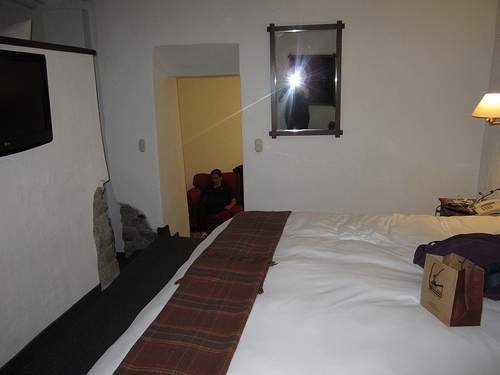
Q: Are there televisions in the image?
A: Yes, there is a television.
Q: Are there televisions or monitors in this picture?
A: Yes, there is a television.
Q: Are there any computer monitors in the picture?
A: No, there are no computer monitors.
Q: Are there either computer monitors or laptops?
A: No, there are no computer monitors or laptops.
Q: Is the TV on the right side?
A: No, the TV is on the left of the image.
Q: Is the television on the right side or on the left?
A: The television is on the left of the image.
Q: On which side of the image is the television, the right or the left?
A: The television is on the left of the image.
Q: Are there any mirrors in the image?
A: Yes, there is a mirror.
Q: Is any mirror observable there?
A: Yes, there is a mirror.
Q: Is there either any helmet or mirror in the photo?
A: Yes, there is a mirror.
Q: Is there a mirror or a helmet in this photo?
A: Yes, there is a mirror.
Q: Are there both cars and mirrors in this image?
A: No, there is a mirror but no cars.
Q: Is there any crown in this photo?
A: No, there are no crowns.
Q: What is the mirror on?
A: The mirror is on the wall.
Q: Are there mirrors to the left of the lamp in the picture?
A: Yes, there is a mirror to the left of the lamp.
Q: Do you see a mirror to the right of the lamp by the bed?
A: No, the mirror is to the left of the lamp.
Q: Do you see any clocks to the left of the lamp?
A: No, there is a mirror to the left of the lamp.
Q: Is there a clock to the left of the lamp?
A: No, there is a mirror to the left of the lamp.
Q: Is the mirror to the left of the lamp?
A: Yes, the mirror is to the left of the lamp.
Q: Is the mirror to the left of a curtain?
A: No, the mirror is to the left of the lamp.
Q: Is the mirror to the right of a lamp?
A: No, the mirror is to the left of a lamp.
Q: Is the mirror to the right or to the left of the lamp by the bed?
A: The mirror is to the left of the lamp.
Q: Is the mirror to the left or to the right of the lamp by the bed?
A: The mirror is to the left of the lamp.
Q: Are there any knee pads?
A: No, there are no knee pads.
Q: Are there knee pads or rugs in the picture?
A: No, there are no knee pads or rugs.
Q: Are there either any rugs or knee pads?
A: No, there are no knee pads or rugs.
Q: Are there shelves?
A: No, there are no shelves.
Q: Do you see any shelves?
A: No, there are no shelves.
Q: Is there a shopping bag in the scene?
A: Yes, there is a shopping bag.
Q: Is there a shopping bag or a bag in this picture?
A: Yes, there is a shopping bag.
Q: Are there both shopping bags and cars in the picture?
A: No, there is a shopping bag but no cars.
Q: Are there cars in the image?
A: No, there are no cars.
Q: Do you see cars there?
A: No, there are no cars.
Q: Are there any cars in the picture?
A: No, there are no cars.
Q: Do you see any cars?
A: No, there are no cars.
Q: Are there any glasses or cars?
A: No, there are no cars or glasses.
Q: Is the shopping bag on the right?
A: Yes, the shopping bag is on the right of the image.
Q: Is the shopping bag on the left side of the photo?
A: No, the shopping bag is on the right of the image.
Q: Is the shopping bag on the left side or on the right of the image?
A: The shopping bag is on the right of the image.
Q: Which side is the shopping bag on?
A: The shopping bag is on the right of the image.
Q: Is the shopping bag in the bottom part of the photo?
A: Yes, the shopping bag is in the bottom of the image.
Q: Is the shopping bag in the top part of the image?
A: No, the shopping bag is in the bottom of the image.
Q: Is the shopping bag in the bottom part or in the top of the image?
A: The shopping bag is in the bottom of the image.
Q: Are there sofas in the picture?
A: Yes, there is a sofa.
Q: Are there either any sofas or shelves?
A: Yes, there is a sofa.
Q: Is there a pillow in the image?
A: No, there are no pillows.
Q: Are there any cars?
A: No, there are no cars.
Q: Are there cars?
A: No, there are no cars.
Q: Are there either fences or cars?
A: No, there are no cars or fences.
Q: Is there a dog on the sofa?
A: No, there is a person on the sofa.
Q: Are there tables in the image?
A: Yes, there is a table.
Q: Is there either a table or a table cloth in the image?
A: Yes, there is a table.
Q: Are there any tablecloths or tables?
A: Yes, there is a table.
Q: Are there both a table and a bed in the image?
A: Yes, there are both a table and a bed.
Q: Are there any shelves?
A: No, there are no shelves.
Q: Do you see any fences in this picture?
A: No, there are no fences.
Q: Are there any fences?
A: No, there are no fences.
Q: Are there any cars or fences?
A: No, there are no fences or cars.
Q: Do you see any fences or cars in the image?
A: No, there are no fences or cars.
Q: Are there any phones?
A: Yes, there is a phone.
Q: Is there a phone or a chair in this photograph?
A: Yes, there is a phone.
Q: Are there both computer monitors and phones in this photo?
A: No, there is a phone but no computer monitors.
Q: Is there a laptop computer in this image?
A: No, there are no laptops.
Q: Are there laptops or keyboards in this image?
A: No, there are no laptops or keyboards.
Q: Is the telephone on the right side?
A: Yes, the telephone is on the right of the image.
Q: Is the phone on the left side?
A: No, the phone is on the right of the image.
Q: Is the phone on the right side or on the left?
A: The phone is on the right of the image.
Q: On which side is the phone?
A: The phone is on the right of the image.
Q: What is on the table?
A: The phone is on the table.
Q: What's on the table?
A: The phone is on the table.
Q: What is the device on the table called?
A: The device is a phone.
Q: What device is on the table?
A: The device is a phone.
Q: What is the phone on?
A: The phone is on the table.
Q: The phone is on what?
A: The phone is on the table.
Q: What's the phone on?
A: The phone is on the table.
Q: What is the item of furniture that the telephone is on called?
A: The piece of furniture is a table.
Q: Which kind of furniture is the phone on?
A: The telephone is on the table.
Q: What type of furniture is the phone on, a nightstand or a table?
A: The phone is on a table.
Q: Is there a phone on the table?
A: Yes, there is a phone on the table.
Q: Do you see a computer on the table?
A: No, there is a phone on the table.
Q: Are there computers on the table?
A: No, there is a phone on the table.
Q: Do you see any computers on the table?
A: No, there is a phone on the table.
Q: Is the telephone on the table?
A: Yes, the telephone is on the table.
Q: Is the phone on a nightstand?
A: No, the phone is on the table.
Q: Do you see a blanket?
A: Yes, there is a blanket.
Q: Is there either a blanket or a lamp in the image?
A: Yes, there is a blanket.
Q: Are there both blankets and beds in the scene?
A: Yes, there are both a blanket and a bed.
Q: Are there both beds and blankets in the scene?
A: Yes, there are both a blanket and a bed.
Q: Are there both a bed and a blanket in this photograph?
A: Yes, there are both a blanket and a bed.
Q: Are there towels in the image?
A: No, there are no towels.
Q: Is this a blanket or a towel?
A: This is a blanket.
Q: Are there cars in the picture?
A: No, there are no cars.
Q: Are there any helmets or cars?
A: No, there are no cars or helmets.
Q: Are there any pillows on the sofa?
A: No, there is a person on the sofa.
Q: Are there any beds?
A: Yes, there is a bed.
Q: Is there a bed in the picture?
A: Yes, there is a bed.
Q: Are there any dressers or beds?
A: Yes, there is a bed.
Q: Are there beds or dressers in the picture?
A: Yes, there is a bed.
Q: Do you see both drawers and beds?
A: No, there is a bed but no drawers.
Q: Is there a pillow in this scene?
A: No, there are no pillows.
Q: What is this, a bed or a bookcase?
A: This is a bed.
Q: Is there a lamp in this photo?
A: Yes, there is a lamp.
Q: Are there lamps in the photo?
A: Yes, there is a lamp.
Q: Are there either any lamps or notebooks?
A: Yes, there is a lamp.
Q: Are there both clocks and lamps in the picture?
A: No, there is a lamp but no clocks.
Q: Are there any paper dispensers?
A: No, there are no paper dispensers.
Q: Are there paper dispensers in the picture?
A: No, there are no paper dispensers.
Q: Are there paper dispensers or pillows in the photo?
A: No, there are no paper dispensers or pillows.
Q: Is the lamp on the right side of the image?
A: Yes, the lamp is on the right of the image.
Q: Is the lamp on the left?
A: No, the lamp is on the right of the image.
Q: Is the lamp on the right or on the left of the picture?
A: The lamp is on the right of the image.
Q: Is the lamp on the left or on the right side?
A: The lamp is on the right of the image.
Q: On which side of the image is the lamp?
A: The lamp is on the right of the image.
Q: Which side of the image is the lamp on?
A: The lamp is on the right of the image.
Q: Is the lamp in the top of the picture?
A: Yes, the lamp is in the top of the image.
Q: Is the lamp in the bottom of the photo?
A: No, the lamp is in the top of the image.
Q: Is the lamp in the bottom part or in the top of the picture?
A: The lamp is in the top of the image.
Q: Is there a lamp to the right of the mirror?
A: Yes, there is a lamp to the right of the mirror.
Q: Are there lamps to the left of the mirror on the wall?
A: No, the lamp is to the right of the mirror.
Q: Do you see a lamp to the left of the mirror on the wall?
A: No, the lamp is to the right of the mirror.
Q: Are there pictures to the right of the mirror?
A: No, there is a lamp to the right of the mirror.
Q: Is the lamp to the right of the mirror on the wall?
A: Yes, the lamp is to the right of the mirror.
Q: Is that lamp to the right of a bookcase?
A: No, the lamp is to the right of the mirror.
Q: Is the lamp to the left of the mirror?
A: No, the lamp is to the right of the mirror.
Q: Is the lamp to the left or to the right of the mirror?
A: The lamp is to the right of the mirror.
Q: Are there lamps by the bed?
A: Yes, there is a lamp by the bed.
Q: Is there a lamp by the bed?
A: Yes, there is a lamp by the bed.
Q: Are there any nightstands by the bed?
A: No, there is a lamp by the bed.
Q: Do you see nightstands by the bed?
A: No, there is a lamp by the bed.